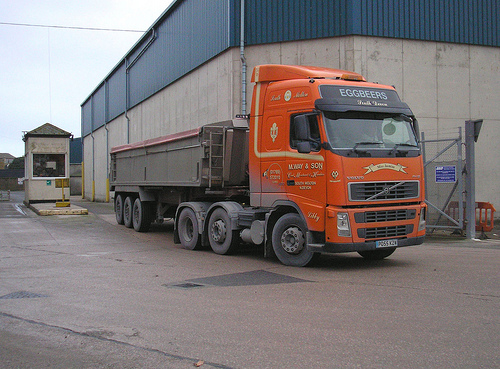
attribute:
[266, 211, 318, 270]
wheel — righ, tire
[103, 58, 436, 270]
truck — orange, large, grey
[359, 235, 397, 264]
wheel — tire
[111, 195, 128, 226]
tire — back, black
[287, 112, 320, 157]
window — passenger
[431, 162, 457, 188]
sign — blue, white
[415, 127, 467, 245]
fence — chain link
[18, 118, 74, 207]
booth — small, security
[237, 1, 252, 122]
pipe — drainage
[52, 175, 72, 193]
sign — yellow